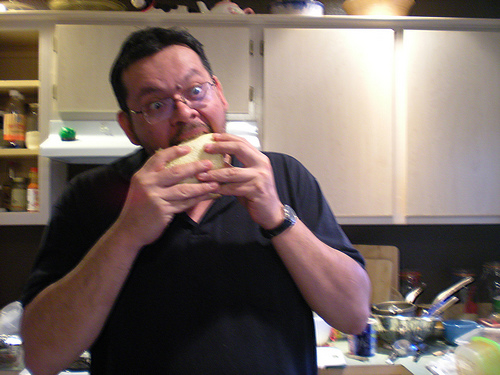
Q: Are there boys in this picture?
A: No, there are no boys.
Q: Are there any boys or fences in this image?
A: No, there are no boys or fences.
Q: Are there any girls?
A: No, there are no girls.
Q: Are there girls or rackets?
A: No, there are no girls or rackets.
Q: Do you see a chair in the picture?
A: No, there are no chairs.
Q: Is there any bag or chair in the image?
A: No, there are no chairs or bags.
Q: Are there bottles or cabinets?
A: Yes, there is a bottle.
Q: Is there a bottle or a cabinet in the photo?
A: Yes, there is a bottle.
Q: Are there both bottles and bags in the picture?
A: No, there is a bottle but no bags.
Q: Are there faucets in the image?
A: No, there are no faucets.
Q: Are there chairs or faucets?
A: No, there are no faucets or chairs.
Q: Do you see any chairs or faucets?
A: No, there are no faucets or chairs.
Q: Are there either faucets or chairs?
A: No, there are no faucets or chairs.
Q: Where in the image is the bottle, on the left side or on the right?
A: The bottle is on the left of the image.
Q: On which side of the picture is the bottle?
A: The bottle is on the left of the image.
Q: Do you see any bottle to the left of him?
A: Yes, there is a bottle to the left of the guy.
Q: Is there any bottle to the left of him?
A: Yes, there is a bottle to the left of the guy.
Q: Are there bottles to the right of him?
A: No, the bottle is to the left of the guy.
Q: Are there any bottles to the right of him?
A: No, the bottle is to the left of the guy.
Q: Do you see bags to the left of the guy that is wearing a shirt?
A: No, there is a bottle to the left of the guy.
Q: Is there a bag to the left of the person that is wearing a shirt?
A: No, there is a bottle to the left of the guy.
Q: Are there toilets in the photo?
A: No, there are no toilets.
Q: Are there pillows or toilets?
A: No, there are no toilets or pillows.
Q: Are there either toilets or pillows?
A: No, there are no toilets or pillows.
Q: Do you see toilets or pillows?
A: No, there are no toilets or pillows.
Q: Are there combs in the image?
A: No, there are no combs.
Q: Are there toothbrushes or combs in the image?
A: No, there are no combs or toothbrushes.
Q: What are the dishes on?
A: The dishes are on the counter.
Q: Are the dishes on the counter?
A: Yes, the dishes are on the counter.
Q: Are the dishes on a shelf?
A: No, the dishes are on the counter.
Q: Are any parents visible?
A: No, there are no parents.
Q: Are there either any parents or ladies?
A: No, there are no parents or ladies.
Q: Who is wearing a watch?
A: The guy is wearing a watch.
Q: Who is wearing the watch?
A: The guy is wearing a watch.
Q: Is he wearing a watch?
A: Yes, the guy is wearing a watch.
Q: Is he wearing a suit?
A: No, the guy is wearing a watch.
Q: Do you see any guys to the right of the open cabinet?
A: Yes, there is a guy to the right of the cabinet.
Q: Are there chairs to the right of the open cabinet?
A: No, there is a guy to the right of the cabinet.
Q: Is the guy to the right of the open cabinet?
A: Yes, the guy is to the right of the cabinet.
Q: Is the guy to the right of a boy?
A: No, the guy is to the right of the cabinet.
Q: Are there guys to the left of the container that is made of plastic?
A: Yes, there is a guy to the left of the container.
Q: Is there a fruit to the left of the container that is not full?
A: No, there is a guy to the left of the container.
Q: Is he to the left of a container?
A: Yes, the guy is to the left of a container.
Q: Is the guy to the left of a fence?
A: No, the guy is to the left of a container.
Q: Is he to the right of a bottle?
A: Yes, the guy is to the right of a bottle.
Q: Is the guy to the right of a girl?
A: No, the guy is to the right of a bottle.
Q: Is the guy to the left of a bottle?
A: No, the guy is to the right of a bottle.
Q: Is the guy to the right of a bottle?
A: Yes, the guy is to the right of a bottle.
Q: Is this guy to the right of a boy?
A: No, the guy is to the right of a bottle.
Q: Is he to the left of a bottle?
A: No, the guy is to the right of a bottle.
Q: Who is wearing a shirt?
A: The guy is wearing a shirt.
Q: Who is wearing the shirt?
A: The guy is wearing a shirt.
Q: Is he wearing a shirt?
A: Yes, the guy is wearing a shirt.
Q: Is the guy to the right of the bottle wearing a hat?
A: No, the guy is wearing a shirt.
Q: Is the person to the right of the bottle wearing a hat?
A: No, the guy is wearing a shirt.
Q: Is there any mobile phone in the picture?
A: No, there are no cell phones.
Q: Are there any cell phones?
A: No, there are no cell phones.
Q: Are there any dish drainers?
A: No, there are no dish drainers.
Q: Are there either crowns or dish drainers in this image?
A: No, there are no dish drainers or crowns.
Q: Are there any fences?
A: No, there are no fences.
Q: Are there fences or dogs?
A: No, there are no fences or dogs.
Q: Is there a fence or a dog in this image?
A: No, there are no fences or dogs.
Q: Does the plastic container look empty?
A: Yes, the container is empty.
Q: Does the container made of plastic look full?
A: No, the container is empty.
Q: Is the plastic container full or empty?
A: The container is empty.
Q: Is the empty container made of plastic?
A: Yes, the container is made of plastic.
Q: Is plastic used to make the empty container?
A: Yes, the container is made of plastic.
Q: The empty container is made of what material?
A: The container is made of plastic.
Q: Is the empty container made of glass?
A: No, the container is made of plastic.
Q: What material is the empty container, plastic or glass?
A: The container is made of plastic.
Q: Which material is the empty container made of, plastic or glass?
A: The container is made of plastic.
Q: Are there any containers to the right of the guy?
A: Yes, there is a container to the right of the guy.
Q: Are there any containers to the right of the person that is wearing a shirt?
A: Yes, there is a container to the right of the guy.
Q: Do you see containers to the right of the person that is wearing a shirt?
A: Yes, there is a container to the right of the guy.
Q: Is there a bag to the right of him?
A: No, there is a container to the right of the guy.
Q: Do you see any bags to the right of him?
A: No, there is a container to the right of the guy.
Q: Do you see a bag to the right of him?
A: No, there is a container to the right of the guy.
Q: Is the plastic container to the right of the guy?
A: Yes, the container is to the right of the guy.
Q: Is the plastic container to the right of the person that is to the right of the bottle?
A: Yes, the container is to the right of the guy.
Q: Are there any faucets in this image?
A: No, there are no faucets.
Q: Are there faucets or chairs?
A: No, there are no faucets or chairs.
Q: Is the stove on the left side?
A: Yes, the stove is on the left of the image.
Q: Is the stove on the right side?
A: No, the stove is on the left of the image.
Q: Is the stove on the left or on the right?
A: The stove is on the left of the image.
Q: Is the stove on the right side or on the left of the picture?
A: The stove is on the left of the image.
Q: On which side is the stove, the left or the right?
A: The stove is on the left of the image.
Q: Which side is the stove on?
A: The stove is on the left of the image.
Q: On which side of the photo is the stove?
A: The stove is on the left of the image.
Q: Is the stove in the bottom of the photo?
A: Yes, the stove is in the bottom of the image.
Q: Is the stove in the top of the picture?
A: No, the stove is in the bottom of the image.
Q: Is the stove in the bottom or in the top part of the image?
A: The stove is in the bottom of the image.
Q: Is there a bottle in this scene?
A: Yes, there is a bottle.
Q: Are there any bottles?
A: Yes, there is a bottle.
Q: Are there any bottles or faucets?
A: Yes, there is a bottle.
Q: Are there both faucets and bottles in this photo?
A: No, there is a bottle but no faucets.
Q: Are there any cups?
A: No, there are no cups.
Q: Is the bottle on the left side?
A: Yes, the bottle is on the left of the image.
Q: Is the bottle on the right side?
A: No, the bottle is on the left of the image.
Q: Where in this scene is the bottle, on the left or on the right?
A: The bottle is on the left of the image.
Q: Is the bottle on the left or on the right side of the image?
A: The bottle is on the left of the image.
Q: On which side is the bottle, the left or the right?
A: The bottle is on the left of the image.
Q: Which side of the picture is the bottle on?
A: The bottle is on the left of the image.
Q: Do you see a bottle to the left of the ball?
A: Yes, there is a bottle to the left of the ball.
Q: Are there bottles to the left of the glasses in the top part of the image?
A: Yes, there is a bottle to the left of the glasses.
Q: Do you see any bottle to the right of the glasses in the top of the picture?
A: No, the bottle is to the left of the glasses.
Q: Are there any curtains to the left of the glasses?
A: No, there is a bottle to the left of the glasses.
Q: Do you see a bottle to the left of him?
A: Yes, there is a bottle to the left of the guy.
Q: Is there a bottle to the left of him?
A: Yes, there is a bottle to the left of the guy.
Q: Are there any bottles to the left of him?
A: Yes, there is a bottle to the left of the guy.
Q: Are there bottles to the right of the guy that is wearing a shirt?
A: No, the bottle is to the left of the guy.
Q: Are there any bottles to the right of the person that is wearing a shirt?
A: No, the bottle is to the left of the guy.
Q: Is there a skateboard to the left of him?
A: No, there is a bottle to the left of the guy.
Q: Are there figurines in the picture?
A: No, there are no figurines.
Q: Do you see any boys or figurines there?
A: No, there are no figurines or boys.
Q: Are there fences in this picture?
A: No, there are no fences.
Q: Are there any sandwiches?
A: Yes, there is a sandwich.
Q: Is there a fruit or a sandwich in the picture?
A: Yes, there is a sandwich.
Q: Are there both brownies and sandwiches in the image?
A: No, there is a sandwich but no brownies.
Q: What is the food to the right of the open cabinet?
A: The food is a sandwich.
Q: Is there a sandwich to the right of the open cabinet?
A: Yes, there is a sandwich to the right of the cabinet.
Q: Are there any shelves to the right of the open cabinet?
A: No, there is a sandwich to the right of the cabinet.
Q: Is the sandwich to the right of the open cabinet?
A: Yes, the sandwich is to the right of the cabinet.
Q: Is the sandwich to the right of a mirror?
A: No, the sandwich is to the right of the cabinet.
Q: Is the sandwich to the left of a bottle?
A: No, the sandwich is to the right of a bottle.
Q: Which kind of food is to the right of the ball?
A: The food is a sandwich.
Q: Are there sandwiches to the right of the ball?
A: Yes, there is a sandwich to the right of the ball.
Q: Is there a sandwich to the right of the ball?
A: Yes, there is a sandwich to the right of the ball.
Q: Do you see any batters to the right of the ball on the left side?
A: No, there is a sandwich to the right of the ball.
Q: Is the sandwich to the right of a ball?
A: Yes, the sandwich is to the right of a ball.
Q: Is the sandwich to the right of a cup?
A: No, the sandwich is to the right of a ball.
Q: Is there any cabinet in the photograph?
A: Yes, there is a cabinet.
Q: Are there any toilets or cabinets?
A: Yes, there is a cabinet.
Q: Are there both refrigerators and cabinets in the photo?
A: No, there is a cabinet but no refrigerators.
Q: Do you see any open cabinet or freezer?
A: Yes, there is an open cabinet.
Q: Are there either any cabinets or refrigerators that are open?
A: Yes, the cabinet is open.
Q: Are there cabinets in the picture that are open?
A: Yes, there is an open cabinet.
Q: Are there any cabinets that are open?
A: Yes, there is a cabinet that is open.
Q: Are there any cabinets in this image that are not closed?
A: Yes, there is a open cabinet.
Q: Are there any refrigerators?
A: No, there are no refrigerators.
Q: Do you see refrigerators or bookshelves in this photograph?
A: No, there are no refrigerators or bookshelves.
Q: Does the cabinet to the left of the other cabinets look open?
A: Yes, the cabinet is open.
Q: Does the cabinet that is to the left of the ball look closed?
A: No, the cabinet is open.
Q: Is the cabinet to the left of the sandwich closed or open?
A: The cabinet is open.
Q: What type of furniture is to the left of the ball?
A: The piece of furniture is a cabinet.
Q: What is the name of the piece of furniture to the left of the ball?
A: The piece of furniture is a cabinet.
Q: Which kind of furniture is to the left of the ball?
A: The piece of furniture is a cabinet.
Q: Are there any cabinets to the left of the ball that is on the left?
A: Yes, there is a cabinet to the left of the ball.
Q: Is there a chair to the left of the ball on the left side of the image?
A: No, there is a cabinet to the left of the ball.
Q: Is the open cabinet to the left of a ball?
A: Yes, the cabinet is to the left of a ball.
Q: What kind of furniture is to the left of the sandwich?
A: The piece of furniture is a cabinet.